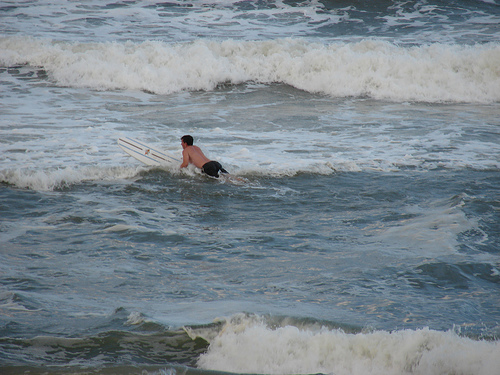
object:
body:
[179, 144, 244, 183]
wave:
[0, 21, 500, 105]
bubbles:
[194, 312, 499, 374]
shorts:
[200, 160, 228, 177]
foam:
[9, 35, 499, 102]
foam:
[0, 115, 492, 190]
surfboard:
[115, 135, 184, 166]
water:
[0, 0, 500, 375]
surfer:
[178, 134, 231, 179]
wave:
[188, 311, 498, 375]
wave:
[0, 145, 499, 199]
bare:
[181, 145, 212, 168]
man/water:
[180, 134, 232, 180]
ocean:
[0, 0, 500, 375]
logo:
[145, 149, 150, 156]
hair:
[181, 135, 194, 146]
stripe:
[119, 143, 161, 163]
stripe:
[118, 138, 172, 163]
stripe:
[125, 136, 179, 161]